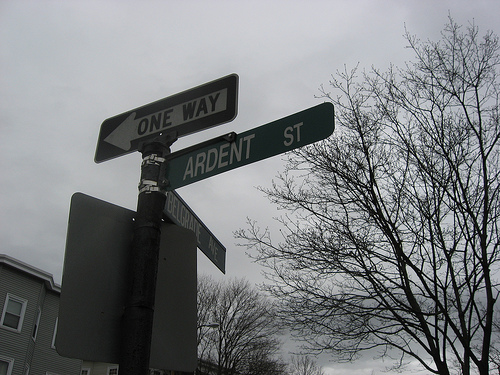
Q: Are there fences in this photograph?
A: No, there are no fences.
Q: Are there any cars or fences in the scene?
A: No, there are no fences or cars.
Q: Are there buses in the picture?
A: No, there are no buses.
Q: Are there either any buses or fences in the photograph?
A: No, there are no buses or fences.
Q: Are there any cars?
A: No, there are no cars.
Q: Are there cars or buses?
A: No, there are no cars or buses.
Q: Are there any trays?
A: No, there are no trays.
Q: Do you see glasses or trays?
A: No, there are no trays or glasses.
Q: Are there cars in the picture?
A: No, there are no cars.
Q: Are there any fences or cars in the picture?
A: No, there are no cars or fences.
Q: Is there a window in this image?
A: Yes, there is a window.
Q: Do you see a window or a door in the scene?
A: Yes, there is a window.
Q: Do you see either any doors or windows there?
A: Yes, there is a window.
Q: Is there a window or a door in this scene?
A: Yes, there is a window.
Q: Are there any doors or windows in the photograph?
A: Yes, there is a window.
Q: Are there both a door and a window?
A: No, there is a window but no doors.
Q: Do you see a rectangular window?
A: Yes, there is a rectangular window.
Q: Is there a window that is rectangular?
A: Yes, there is a window that is rectangular.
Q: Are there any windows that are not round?
A: Yes, there is a rectangular window.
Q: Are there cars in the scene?
A: No, there are no cars.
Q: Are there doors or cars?
A: No, there are no cars or doors.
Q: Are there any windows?
A: Yes, there is a window.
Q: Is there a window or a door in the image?
A: Yes, there is a window.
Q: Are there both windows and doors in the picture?
A: No, there is a window but no doors.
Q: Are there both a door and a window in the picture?
A: No, there is a window but no doors.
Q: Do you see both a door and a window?
A: No, there is a window but no doors.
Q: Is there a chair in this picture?
A: No, there are no chairs.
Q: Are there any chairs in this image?
A: No, there are no chairs.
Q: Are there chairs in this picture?
A: No, there are no chairs.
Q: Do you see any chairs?
A: No, there are no chairs.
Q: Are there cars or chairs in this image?
A: No, there are no chairs or cars.